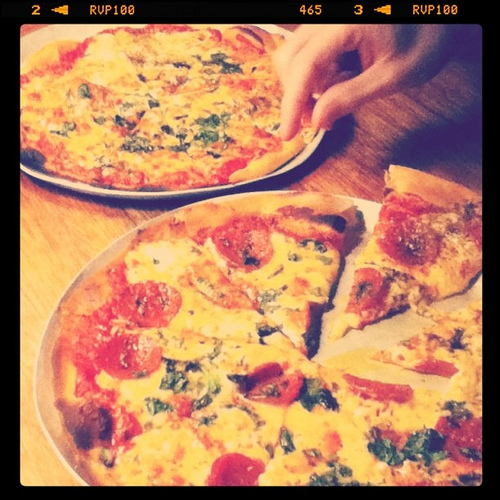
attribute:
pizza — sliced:
[335, 160, 495, 347]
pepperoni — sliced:
[120, 281, 182, 328]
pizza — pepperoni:
[35, 160, 491, 500]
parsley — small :
[302, 375, 337, 407]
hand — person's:
[275, 28, 482, 138]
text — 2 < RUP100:
[29, 0, 138, 19]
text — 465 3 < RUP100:
[295, 0, 463, 19]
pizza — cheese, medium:
[24, 26, 321, 192]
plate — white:
[33, 191, 499, 485]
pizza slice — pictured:
[340, 158, 483, 339]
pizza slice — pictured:
[187, 192, 360, 354]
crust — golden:
[18, 181, 472, 491]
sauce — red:
[85, 160, 233, 190]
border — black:
[2, 2, 498, 496]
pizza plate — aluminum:
[27, 178, 479, 485]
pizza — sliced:
[344, 157, 486, 337]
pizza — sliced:
[330, 159, 483, 339]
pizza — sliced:
[182, 191, 358, 349]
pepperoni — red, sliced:
[209, 212, 269, 268]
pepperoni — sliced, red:
[371, 211, 448, 271]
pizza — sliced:
[316, 171, 463, 372]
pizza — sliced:
[179, 172, 363, 351]